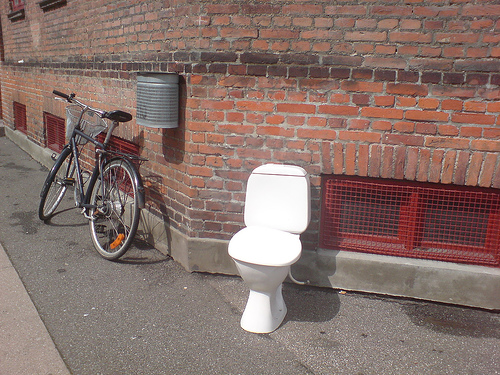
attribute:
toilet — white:
[222, 159, 317, 339]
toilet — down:
[196, 173, 346, 340]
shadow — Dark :
[33, 94, 150, 258]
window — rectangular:
[328, 173, 492, 268]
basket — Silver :
[62, 109, 129, 141]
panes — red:
[91, 130, 143, 190]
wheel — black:
[24, 144, 86, 228]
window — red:
[305, 160, 499, 272]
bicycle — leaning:
[58, 101, 122, 226]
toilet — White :
[212, 140, 331, 350]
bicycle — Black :
[15, 79, 172, 273]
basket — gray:
[45, 97, 97, 158]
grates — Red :
[321, 172, 498, 269]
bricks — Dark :
[1, 43, 496, 80]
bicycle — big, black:
[49, 96, 160, 261]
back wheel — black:
[82, 154, 146, 261]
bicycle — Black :
[37, 83, 154, 270]